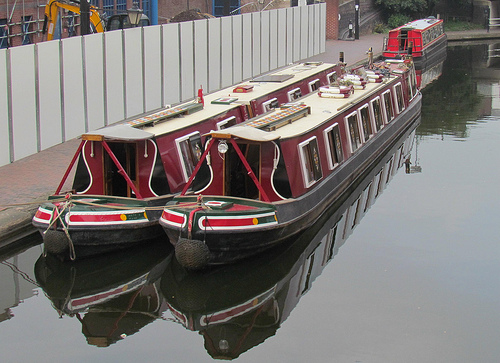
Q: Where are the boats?
A: In the water.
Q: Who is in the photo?
A: There are no people.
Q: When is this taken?
A: During the day time.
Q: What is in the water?
A: Boats.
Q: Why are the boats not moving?
A: They are docked.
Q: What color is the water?
A: Gray.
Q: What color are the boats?
A: Red.